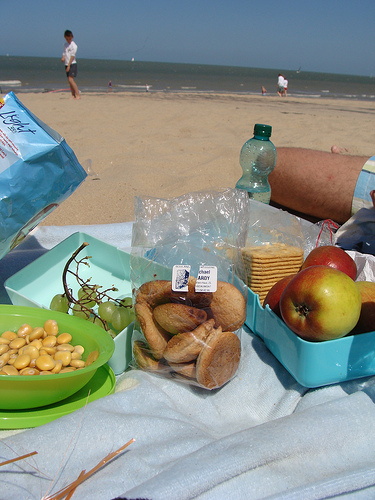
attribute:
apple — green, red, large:
[280, 265, 357, 337]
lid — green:
[251, 121, 274, 140]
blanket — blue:
[0, 214, 364, 497]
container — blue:
[6, 231, 172, 376]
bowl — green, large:
[0, 300, 112, 413]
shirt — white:
[60, 42, 79, 67]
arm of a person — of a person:
[61, 44, 94, 81]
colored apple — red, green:
[258, 233, 370, 356]